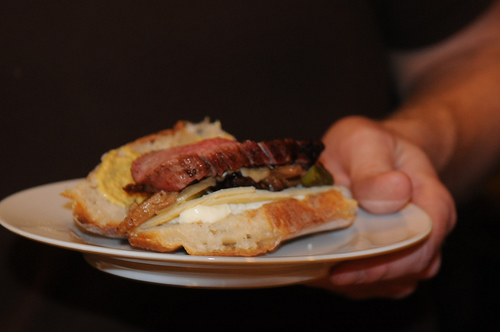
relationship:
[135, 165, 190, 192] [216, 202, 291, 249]
meat on roll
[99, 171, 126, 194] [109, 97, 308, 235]
cheese on sandwhich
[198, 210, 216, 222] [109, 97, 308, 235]
mayonnaise on sandwhich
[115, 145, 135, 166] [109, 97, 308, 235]
mustard on sandwhich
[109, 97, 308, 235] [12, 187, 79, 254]
sandwhich on plate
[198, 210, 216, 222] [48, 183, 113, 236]
mayonnaise on bread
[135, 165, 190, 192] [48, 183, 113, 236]
meat on bread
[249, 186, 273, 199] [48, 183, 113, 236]
egg on bread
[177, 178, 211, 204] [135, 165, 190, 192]
onions under meat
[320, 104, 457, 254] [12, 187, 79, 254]
hand holding plate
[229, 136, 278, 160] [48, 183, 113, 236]
hot dog on bread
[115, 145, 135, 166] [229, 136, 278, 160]
mustard on hot dog